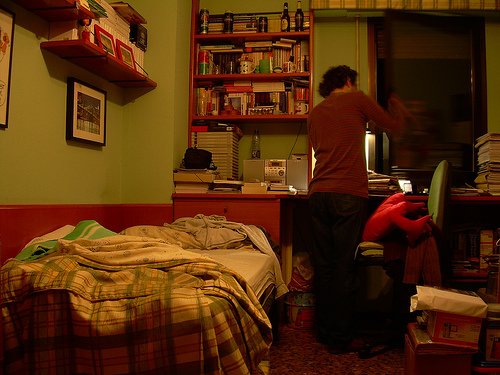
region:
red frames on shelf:
[76, 14, 166, 87]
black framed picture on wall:
[56, 67, 123, 169]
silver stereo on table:
[242, 147, 336, 211]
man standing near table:
[296, 38, 398, 369]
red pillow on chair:
[361, 173, 436, 256]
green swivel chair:
[326, 137, 457, 353]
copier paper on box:
[393, 264, 499, 336]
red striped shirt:
[289, 57, 399, 228]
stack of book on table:
[473, 118, 498, 216]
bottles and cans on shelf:
[198, 4, 330, 44]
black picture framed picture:
[38, 70, 153, 159]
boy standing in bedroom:
[286, 40, 421, 372]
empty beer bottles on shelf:
[194, 0, 314, 42]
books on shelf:
[161, 30, 313, 222]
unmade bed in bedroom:
[1, 190, 291, 373]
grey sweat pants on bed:
[153, 195, 302, 302]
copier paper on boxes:
[392, 265, 499, 340]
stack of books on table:
[463, 120, 498, 202]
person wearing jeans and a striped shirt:
[316, 65, 361, 342]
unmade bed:
[62, 220, 262, 339]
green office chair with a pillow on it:
[363, 160, 451, 269]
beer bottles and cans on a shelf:
[198, 4, 305, 32]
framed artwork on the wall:
[60, 78, 113, 145]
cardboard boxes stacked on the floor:
[402, 315, 494, 373]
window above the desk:
[373, 13, 481, 178]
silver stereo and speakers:
[246, 158, 307, 188]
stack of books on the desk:
[473, 131, 498, 193]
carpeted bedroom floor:
[271, 353, 373, 369]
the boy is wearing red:
[288, 62, 398, 287]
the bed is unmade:
[55, 210, 295, 372]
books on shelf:
[180, 16, 307, 146]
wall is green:
[14, 69, 194, 212]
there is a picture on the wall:
[52, 65, 135, 163]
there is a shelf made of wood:
[38, 29, 202, 134]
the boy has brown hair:
[303, 60, 383, 120]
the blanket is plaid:
[41, 248, 272, 371]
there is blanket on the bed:
[34, 198, 235, 343]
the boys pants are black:
[294, 186, 376, 332]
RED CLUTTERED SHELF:
[164, 1, 328, 161]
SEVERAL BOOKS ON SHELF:
[199, 34, 316, 128]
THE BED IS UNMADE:
[6, 192, 302, 370]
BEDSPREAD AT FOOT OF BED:
[2, 238, 287, 374]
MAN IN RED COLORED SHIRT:
[267, 53, 428, 225]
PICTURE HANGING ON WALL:
[37, 66, 137, 159]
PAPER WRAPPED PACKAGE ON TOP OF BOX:
[402, 258, 495, 363]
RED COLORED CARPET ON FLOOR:
[258, 317, 440, 374]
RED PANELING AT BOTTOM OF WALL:
[0, 193, 186, 263]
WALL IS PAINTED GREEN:
[2, 3, 367, 210]